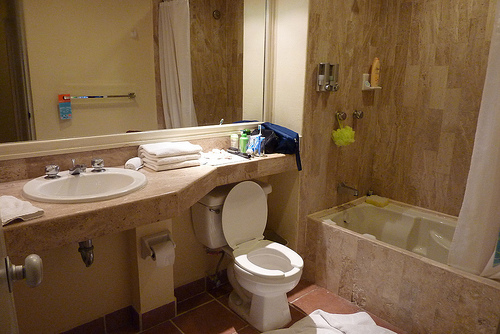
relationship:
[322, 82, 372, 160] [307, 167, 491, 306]
loofah hangings tub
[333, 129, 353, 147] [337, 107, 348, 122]
sponge on handle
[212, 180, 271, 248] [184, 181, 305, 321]
seat of toilet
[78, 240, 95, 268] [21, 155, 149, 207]
pipe under sink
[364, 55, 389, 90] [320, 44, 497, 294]
shampoo in shower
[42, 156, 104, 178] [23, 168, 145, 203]
faucet on sink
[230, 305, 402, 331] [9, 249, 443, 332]
towel on floor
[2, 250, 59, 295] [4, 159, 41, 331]
knob of door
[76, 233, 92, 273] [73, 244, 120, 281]
pipe under sink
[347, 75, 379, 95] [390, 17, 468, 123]
shelf on wall